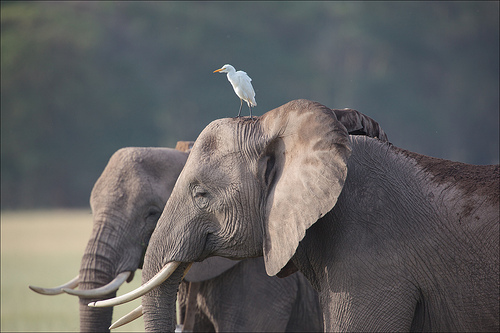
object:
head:
[216, 63, 234, 73]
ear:
[263, 98, 354, 278]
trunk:
[63, 267, 135, 301]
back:
[349, 132, 499, 332]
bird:
[212, 64, 259, 123]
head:
[82, 100, 353, 333]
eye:
[193, 190, 210, 198]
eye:
[146, 210, 161, 215]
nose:
[77, 226, 120, 333]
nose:
[138, 251, 194, 333]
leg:
[313, 272, 417, 333]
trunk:
[89, 259, 185, 311]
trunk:
[107, 300, 164, 329]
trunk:
[86, 262, 177, 311]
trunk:
[23, 275, 82, 297]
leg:
[233, 99, 245, 119]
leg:
[249, 103, 253, 120]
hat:
[212, 62, 262, 117]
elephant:
[83, 99, 500, 333]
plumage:
[229, 72, 254, 104]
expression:
[134, 201, 161, 229]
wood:
[174, 139, 194, 151]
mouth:
[194, 227, 212, 261]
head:
[28, 146, 189, 333]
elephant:
[28, 141, 325, 332]